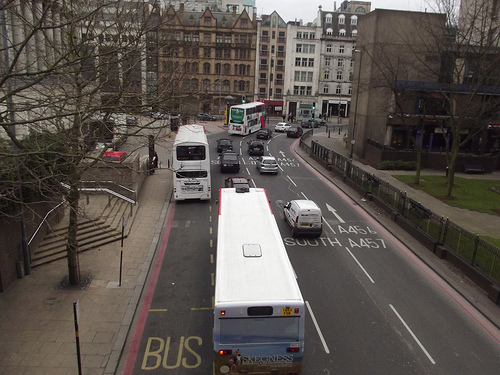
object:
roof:
[214, 185, 307, 306]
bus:
[211, 186, 321, 374]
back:
[213, 305, 304, 374]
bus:
[140, 335, 205, 370]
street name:
[284, 237, 387, 249]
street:
[116, 121, 500, 372]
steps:
[30, 233, 136, 268]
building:
[0, 0, 94, 291]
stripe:
[119, 200, 177, 373]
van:
[281, 198, 323, 236]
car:
[272, 122, 288, 132]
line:
[264, 129, 436, 364]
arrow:
[324, 201, 345, 225]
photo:
[0, 1, 499, 374]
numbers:
[346, 235, 387, 251]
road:
[114, 126, 499, 372]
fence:
[298, 138, 500, 300]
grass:
[395, 173, 499, 216]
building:
[341, 8, 497, 170]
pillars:
[12, 2, 26, 76]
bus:
[225, 102, 267, 135]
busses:
[170, 123, 210, 200]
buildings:
[280, 1, 371, 121]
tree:
[3, 0, 203, 288]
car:
[256, 154, 278, 174]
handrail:
[26, 179, 135, 268]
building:
[157, 7, 259, 118]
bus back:
[228, 107, 245, 136]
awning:
[260, 100, 284, 107]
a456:
[336, 223, 377, 235]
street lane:
[117, 135, 211, 374]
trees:
[391, 0, 497, 197]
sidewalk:
[304, 129, 500, 239]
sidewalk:
[0, 119, 174, 374]